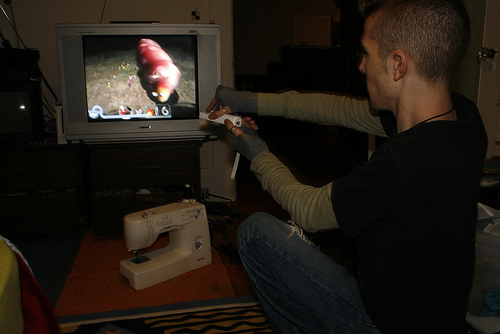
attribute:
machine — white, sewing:
[122, 197, 211, 290]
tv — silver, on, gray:
[58, 23, 224, 144]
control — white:
[199, 108, 242, 132]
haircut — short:
[367, 2, 466, 87]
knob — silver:
[19, 104, 26, 112]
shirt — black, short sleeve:
[330, 86, 473, 334]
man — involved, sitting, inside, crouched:
[206, 2, 496, 333]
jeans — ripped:
[236, 208, 378, 331]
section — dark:
[234, 1, 367, 280]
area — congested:
[2, 30, 491, 326]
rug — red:
[57, 220, 234, 321]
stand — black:
[87, 139, 203, 249]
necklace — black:
[392, 105, 458, 140]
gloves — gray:
[216, 81, 268, 155]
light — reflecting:
[12, 98, 36, 126]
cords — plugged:
[38, 69, 57, 131]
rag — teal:
[483, 292, 500, 314]